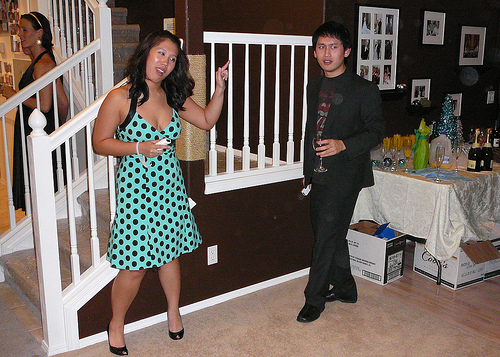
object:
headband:
[28, 13, 42, 28]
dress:
[105, 84, 203, 270]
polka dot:
[172, 202, 176, 207]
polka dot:
[171, 237, 175, 243]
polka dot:
[134, 178, 140, 184]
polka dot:
[126, 224, 131, 230]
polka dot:
[169, 126, 175, 132]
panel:
[207, 245, 219, 266]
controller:
[136, 138, 172, 169]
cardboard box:
[346, 221, 407, 287]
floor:
[0, 237, 500, 357]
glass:
[312, 135, 329, 173]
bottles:
[467, 128, 495, 173]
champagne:
[467, 128, 495, 172]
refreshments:
[371, 118, 500, 182]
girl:
[0, 11, 69, 216]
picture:
[422, 10, 446, 45]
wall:
[322, 0, 500, 131]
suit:
[301, 66, 385, 312]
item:
[467, 128, 494, 172]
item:
[435, 94, 458, 154]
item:
[434, 145, 445, 183]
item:
[412, 117, 453, 170]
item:
[371, 133, 416, 172]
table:
[372, 159, 500, 286]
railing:
[25, 77, 140, 356]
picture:
[447, 92, 463, 116]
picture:
[458, 25, 486, 65]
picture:
[357, 5, 400, 90]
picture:
[411, 78, 431, 105]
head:
[311, 21, 352, 72]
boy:
[296, 21, 386, 323]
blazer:
[303, 67, 387, 194]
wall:
[194, 93, 282, 145]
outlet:
[207, 245, 219, 266]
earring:
[36, 37, 42, 45]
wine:
[314, 144, 325, 152]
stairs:
[0, 0, 314, 357]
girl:
[91, 29, 230, 356]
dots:
[140, 175, 180, 233]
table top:
[372, 152, 500, 185]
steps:
[0, 187, 116, 316]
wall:
[183, 177, 312, 302]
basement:
[0, 0, 500, 357]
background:
[0, 2, 103, 236]